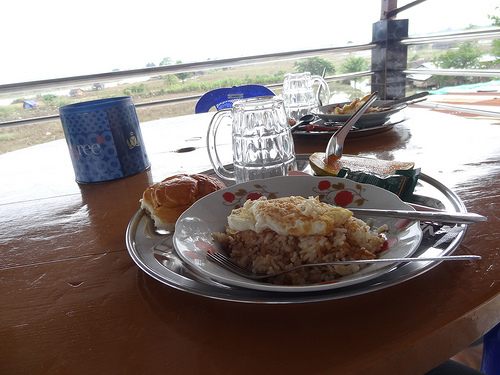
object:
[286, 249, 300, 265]
rice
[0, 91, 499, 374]
table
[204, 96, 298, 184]
cup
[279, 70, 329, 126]
cup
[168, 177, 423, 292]
plate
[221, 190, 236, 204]
roses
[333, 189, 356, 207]
roses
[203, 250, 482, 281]
fork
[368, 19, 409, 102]
post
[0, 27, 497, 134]
guardrail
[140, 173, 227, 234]
roll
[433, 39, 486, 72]
tree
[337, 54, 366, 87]
tree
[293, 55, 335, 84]
tree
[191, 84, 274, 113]
chair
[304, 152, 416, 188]
fruit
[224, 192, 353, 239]
food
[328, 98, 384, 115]
food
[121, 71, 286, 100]
bushes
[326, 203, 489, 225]
knife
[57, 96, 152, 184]
container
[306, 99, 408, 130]
plate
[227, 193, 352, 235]
topping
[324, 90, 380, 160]
spoon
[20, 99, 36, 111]
tent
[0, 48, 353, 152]
ground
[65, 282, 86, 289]
nick